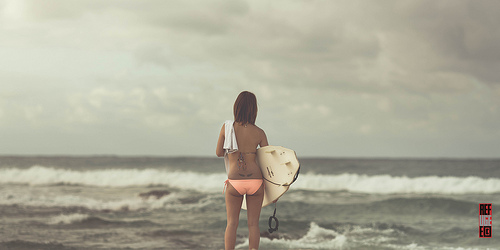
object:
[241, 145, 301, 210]
board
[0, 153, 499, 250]
water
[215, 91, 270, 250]
girl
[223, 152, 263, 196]
bikini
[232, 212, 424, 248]
surf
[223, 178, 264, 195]
bikini bottom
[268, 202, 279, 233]
leash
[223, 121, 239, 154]
shirt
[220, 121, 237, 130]
shoulder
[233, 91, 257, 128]
hair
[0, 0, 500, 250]
away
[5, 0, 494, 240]
weather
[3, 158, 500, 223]
wave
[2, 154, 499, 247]
ocean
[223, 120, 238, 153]
towel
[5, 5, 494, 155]
sky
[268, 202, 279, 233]
tether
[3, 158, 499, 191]
caps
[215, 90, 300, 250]
view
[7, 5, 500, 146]
clouds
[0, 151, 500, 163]
horizon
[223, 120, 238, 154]
something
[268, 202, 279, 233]
strap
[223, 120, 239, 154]
fabric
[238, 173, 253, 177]
tattoo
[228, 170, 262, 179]
lower back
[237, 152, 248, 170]
strings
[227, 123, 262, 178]
back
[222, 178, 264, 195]
bottoms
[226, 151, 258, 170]
top